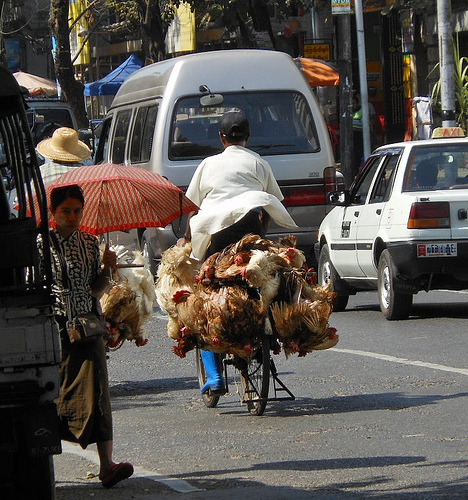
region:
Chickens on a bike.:
[161, 243, 335, 357]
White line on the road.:
[338, 336, 467, 406]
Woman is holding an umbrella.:
[41, 158, 181, 235]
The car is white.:
[327, 133, 466, 305]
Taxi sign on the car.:
[420, 118, 466, 146]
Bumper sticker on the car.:
[408, 238, 467, 262]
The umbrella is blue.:
[81, 53, 159, 98]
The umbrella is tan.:
[11, 66, 61, 96]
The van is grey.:
[128, 65, 349, 227]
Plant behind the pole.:
[429, 52, 467, 127]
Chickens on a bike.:
[153, 243, 343, 353]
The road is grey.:
[333, 393, 437, 497]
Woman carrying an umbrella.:
[41, 172, 176, 270]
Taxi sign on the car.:
[425, 119, 467, 147]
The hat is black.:
[209, 102, 257, 148]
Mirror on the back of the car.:
[191, 82, 236, 111]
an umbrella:
[53, 110, 176, 341]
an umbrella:
[108, 173, 239, 484]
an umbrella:
[94, 106, 148, 274]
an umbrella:
[33, 38, 246, 409]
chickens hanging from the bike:
[154, 235, 342, 366]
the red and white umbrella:
[47, 155, 194, 241]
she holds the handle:
[95, 239, 132, 283]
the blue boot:
[187, 344, 235, 405]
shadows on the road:
[299, 369, 464, 498]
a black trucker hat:
[205, 105, 255, 146]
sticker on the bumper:
[411, 240, 467, 262]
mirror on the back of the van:
[192, 81, 227, 109]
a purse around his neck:
[48, 233, 106, 347]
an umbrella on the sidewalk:
[294, 50, 341, 87]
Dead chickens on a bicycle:
[142, 238, 366, 365]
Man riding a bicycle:
[177, 97, 300, 417]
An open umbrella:
[16, 147, 216, 243]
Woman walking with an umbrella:
[28, 88, 187, 477]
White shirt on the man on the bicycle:
[170, 141, 315, 249]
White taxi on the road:
[325, 107, 461, 327]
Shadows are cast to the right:
[120, 345, 454, 496]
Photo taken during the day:
[15, 0, 446, 492]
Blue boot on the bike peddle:
[172, 326, 239, 409]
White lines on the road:
[50, 314, 465, 481]